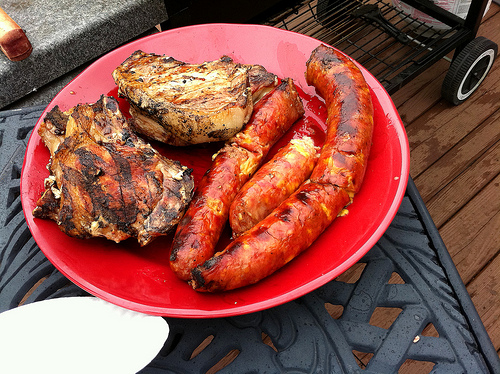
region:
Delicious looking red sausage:
[231, 136, 316, 233]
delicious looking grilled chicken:
[34, 93, 199, 250]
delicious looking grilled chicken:
[116, 43, 278, 148]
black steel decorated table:
[5, 98, 495, 370]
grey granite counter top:
[0, 0, 175, 107]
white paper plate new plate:
[0, 291, 174, 371]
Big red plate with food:
[23, 20, 418, 322]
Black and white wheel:
[440, 31, 496, 106]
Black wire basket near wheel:
[263, 0, 461, 93]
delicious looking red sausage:
[150, 74, 301, 281]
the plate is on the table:
[17, 5, 452, 324]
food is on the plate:
[32, 7, 427, 343]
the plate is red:
[4, 12, 455, 360]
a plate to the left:
[2, 295, 183, 367]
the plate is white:
[5, 283, 177, 370]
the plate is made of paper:
[5, 290, 189, 365]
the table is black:
[340, 262, 489, 366]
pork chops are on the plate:
[26, 19, 228, 226]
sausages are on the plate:
[167, 41, 369, 296]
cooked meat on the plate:
[35, 100, 187, 244]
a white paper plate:
[1, 296, 167, 372]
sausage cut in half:
[229, 131, 312, 228]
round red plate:
[18, 22, 407, 316]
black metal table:
[0, 110, 496, 370]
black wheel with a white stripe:
[443, 36, 496, 105]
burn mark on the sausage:
[195, 254, 220, 286]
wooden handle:
[0, 22, 33, 58]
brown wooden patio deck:
[293, 11, 496, 341]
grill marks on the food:
[75, 147, 179, 232]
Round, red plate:
[20, 23, 408, 318]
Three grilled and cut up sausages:
[170, 45, 375, 297]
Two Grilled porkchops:
[35, 54, 271, 250]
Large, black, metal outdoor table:
[0, 70, 496, 370]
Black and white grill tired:
[443, 30, 494, 101]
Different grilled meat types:
[35, 46, 380, 294]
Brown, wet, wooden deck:
[275, 0, 496, 370]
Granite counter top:
[0, 0, 166, 106]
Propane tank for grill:
[390, 0, 485, 35]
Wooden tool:
[0, 0, 33, 61]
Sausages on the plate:
[213, 124, 348, 249]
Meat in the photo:
[122, 64, 227, 139]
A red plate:
[110, 33, 288, 63]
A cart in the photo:
[377, 31, 452, 80]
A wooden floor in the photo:
[435, 130, 497, 222]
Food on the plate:
[76, 92, 340, 262]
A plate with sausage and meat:
[16, 36, 419, 312]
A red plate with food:
[12, 29, 399, 304]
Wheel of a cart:
[433, 50, 495, 110]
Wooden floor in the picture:
[434, 165, 498, 225]